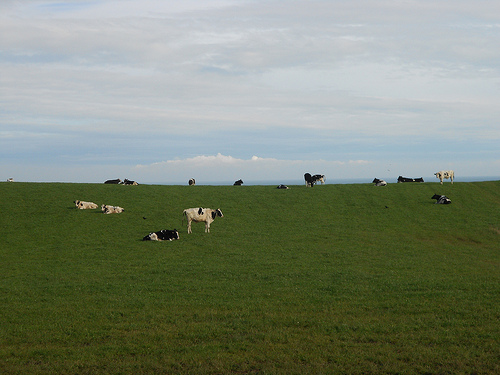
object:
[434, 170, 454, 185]
cow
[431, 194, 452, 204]
cow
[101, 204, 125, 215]
cow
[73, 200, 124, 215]
cows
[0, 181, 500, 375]
grass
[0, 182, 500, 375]
ground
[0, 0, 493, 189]
sun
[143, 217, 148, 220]
bird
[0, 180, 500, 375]
field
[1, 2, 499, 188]
sky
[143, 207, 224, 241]
cows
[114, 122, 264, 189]
wall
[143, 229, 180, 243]
cow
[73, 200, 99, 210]
cow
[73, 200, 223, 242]
four cows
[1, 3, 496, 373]
picture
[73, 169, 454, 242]
cows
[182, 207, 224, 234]
cow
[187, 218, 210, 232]
legs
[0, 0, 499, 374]
outdoor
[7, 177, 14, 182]
farmer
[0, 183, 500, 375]
farm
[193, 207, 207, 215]
spots